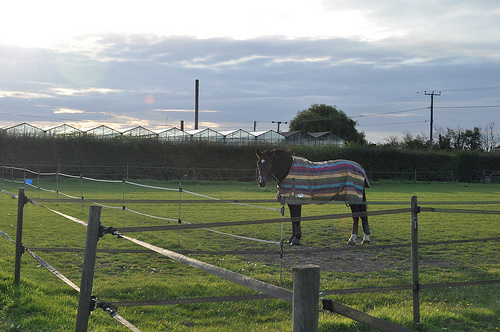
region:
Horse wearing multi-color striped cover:
[250, 143, 377, 248]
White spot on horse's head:
[258, 155, 266, 166]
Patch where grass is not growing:
[237, 234, 447, 274]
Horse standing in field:
[250, 140, 382, 251]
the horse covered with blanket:
[246, 135, 382, 250]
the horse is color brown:
[243, 139, 377, 253]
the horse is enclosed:
[236, 135, 392, 255]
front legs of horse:
[278, 200, 309, 247]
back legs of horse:
[342, 200, 377, 250]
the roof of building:
[0, 110, 370, 155]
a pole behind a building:
[188, 73, 203, 134]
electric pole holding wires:
[387, 80, 475, 140]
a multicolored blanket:
[271, 146, 377, 208]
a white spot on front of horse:
[246, 141, 278, 191]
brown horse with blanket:
[248, 140, 375, 235]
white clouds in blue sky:
[27, 58, 56, 80]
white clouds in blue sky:
[73, 63, 96, 86]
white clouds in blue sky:
[47, 89, 72, 111]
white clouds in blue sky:
[121, 56, 155, 78]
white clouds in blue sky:
[221, 46, 253, 67]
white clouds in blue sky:
[280, 31, 312, 53]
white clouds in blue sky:
[358, 26, 392, 56]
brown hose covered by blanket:
[244, 142, 383, 242]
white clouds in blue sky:
[24, 44, 39, 67]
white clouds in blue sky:
[388, 31, 434, 68]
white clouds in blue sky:
[208, 41, 240, 82]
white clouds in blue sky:
[327, 33, 366, 73]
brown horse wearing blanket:
[253, 147, 371, 246]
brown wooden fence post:
[292, 262, 320, 329]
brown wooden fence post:
[76, 204, 102, 329]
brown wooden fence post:
[14, 187, 24, 282]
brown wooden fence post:
[410, 193, 421, 319]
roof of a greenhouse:
[3, 120, 43, 135]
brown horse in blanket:
[238, 143, 368, 243]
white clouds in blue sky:
[61, 68, 119, 105]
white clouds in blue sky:
[75, 46, 116, 74]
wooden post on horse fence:
[290, 261, 321, 328]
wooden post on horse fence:
[406, 191, 421, 321]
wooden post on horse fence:
[75, 202, 101, 327]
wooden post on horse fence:
[11, 185, 22, 281]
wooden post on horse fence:
[176, 178, 181, 233]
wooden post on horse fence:
[120, 175, 125, 220]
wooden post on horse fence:
[271, 191, 286, 261]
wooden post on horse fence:
[78, 172, 83, 208]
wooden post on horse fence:
[54, 170, 59, 209]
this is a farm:
[49, 62, 440, 314]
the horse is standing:
[246, 156, 355, 249]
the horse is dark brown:
[237, 148, 305, 201]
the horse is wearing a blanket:
[272, 145, 387, 240]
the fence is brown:
[88, 209, 230, 329]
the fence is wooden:
[32, 193, 174, 284]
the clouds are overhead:
[187, 28, 355, 113]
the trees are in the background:
[257, 90, 419, 164]